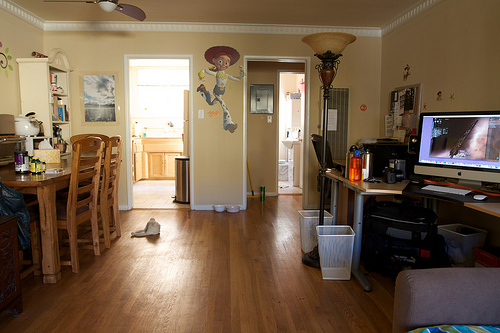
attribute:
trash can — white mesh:
[313, 222, 356, 284]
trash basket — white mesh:
[316, 224, 353, 279]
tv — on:
[410, 111, 498, 185]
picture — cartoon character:
[195, 42, 245, 132]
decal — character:
[195, 41, 245, 136]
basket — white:
[309, 219, 371, 287]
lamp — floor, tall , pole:
[297, 27, 362, 272]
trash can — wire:
[308, 221, 361, 284]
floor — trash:
[206, 232, 325, 310]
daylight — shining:
[127, 56, 189, 139]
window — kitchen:
[130, 59, 188, 129]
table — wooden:
[1, 129, 124, 274]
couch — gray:
[390, 238, 493, 329]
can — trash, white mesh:
[314, 223, 356, 283]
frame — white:
[118, 46, 206, 225]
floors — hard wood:
[183, 208, 283, 328]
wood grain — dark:
[261, 282, 382, 330]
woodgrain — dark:
[82, 270, 348, 329]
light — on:
[278, 76, 302, 167]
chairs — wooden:
[61, 131, 124, 268]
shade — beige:
[301, 29, 357, 56]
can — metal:
[171, 151, 191, 211]